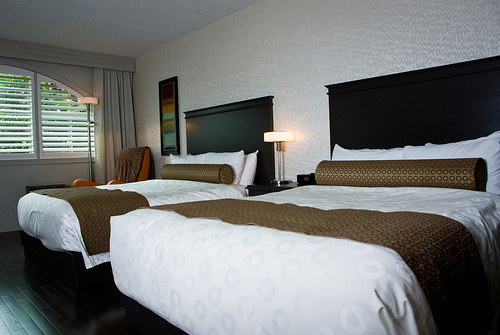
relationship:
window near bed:
[7, 68, 89, 173] [262, 145, 473, 318]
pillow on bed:
[342, 142, 473, 165] [262, 145, 473, 318]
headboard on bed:
[320, 55, 499, 153] [262, 145, 473, 318]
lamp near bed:
[253, 123, 306, 158] [262, 145, 473, 318]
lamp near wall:
[253, 123, 306, 158] [241, 17, 322, 80]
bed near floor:
[262, 145, 473, 318] [24, 269, 88, 331]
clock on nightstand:
[289, 169, 337, 199] [214, 155, 308, 205]